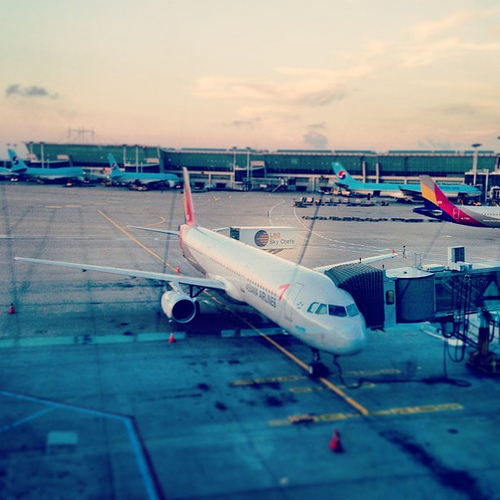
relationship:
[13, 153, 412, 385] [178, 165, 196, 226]
airplane with plane's tail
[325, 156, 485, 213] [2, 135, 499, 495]
airplane at airport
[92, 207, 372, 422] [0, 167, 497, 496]
line on pavement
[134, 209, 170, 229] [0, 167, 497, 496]
line on pavement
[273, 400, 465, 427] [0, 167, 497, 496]
line on pavement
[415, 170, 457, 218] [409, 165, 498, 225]
plane's tail on plane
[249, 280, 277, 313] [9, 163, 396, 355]
company name on plane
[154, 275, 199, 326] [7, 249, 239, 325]
engine underneath wing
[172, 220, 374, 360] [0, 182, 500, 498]
fuselage on tarmac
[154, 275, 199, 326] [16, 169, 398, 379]
engine on jet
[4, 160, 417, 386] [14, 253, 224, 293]
wing on jet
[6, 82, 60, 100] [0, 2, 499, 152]
cloud in sky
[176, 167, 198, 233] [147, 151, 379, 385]
wing on a jet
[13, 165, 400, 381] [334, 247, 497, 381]
airplane docked at gate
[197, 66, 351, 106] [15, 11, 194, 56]
clouds in sky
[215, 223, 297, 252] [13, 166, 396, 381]
truck behind plane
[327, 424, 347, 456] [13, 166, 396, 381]
caution cone in front of a plane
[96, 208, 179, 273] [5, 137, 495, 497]
line painted on tarmac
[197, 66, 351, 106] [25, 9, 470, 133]
clouds in sky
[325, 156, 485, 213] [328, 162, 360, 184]
airplane has plane's tail